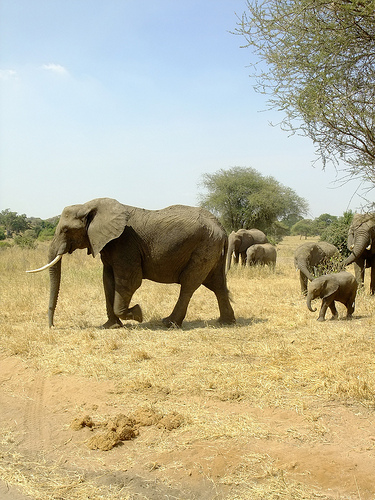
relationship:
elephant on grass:
[23, 195, 241, 339] [8, 253, 373, 499]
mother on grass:
[225, 227, 266, 270] [8, 253, 373, 499]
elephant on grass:
[237, 241, 282, 271] [8, 253, 373, 499]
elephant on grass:
[290, 234, 349, 301] [8, 253, 373, 499]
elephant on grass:
[301, 269, 366, 326] [8, 253, 373, 499]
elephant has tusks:
[23, 195, 241, 339] [19, 252, 64, 274]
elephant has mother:
[246, 244, 277, 274] [225, 227, 266, 270]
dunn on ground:
[64, 402, 197, 459] [49, 375, 206, 478]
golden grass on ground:
[2, 236, 374, 499] [1, 235, 374, 498]